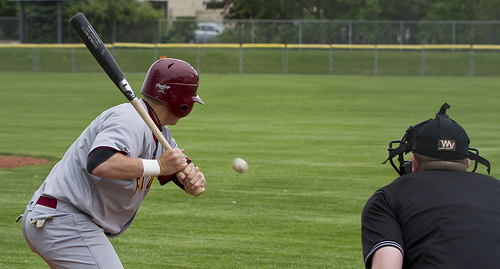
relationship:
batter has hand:
[19, 53, 208, 269] [156, 144, 189, 180]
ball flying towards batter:
[229, 152, 252, 177] [19, 53, 208, 269]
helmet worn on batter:
[140, 57, 206, 121] [19, 53, 208, 269]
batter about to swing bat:
[19, 53, 208, 269] [68, 12, 207, 199]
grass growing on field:
[1, 50, 498, 266] [2, 73, 498, 269]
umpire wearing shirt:
[359, 102, 499, 269] [360, 167, 498, 268]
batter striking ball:
[19, 53, 208, 269] [229, 152, 252, 177]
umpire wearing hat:
[359, 102, 499, 269] [410, 114, 472, 161]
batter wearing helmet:
[19, 53, 208, 269] [140, 57, 206, 121]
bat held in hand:
[68, 12, 207, 199] [156, 144, 189, 180]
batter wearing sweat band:
[19, 53, 208, 269] [139, 155, 163, 180]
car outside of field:
[193, 19, 225, 44] [2, 73, 498, 269]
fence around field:
[1, 14, 499, 80] [2, 73, 498, 269]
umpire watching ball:
[359, 102, 499, 269] [229, 152, 252, 177]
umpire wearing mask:
[359, 102, 499, 269] [386, 125, 492, 175]